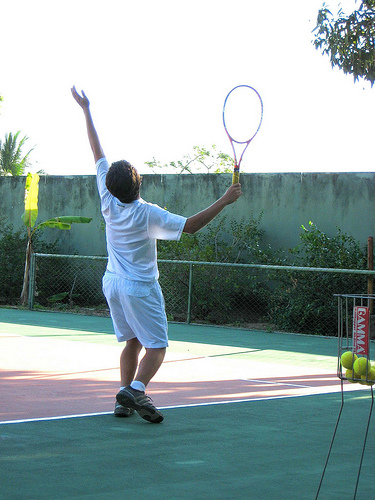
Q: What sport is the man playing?
A: Tennis.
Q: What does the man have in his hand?
A: A tennis racket.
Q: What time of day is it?
A: Daytime.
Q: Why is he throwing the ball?
A: He is serving.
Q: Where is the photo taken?
A: On the tennis court.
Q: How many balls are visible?
A: Four.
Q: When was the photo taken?
A: During the day.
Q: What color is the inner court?
A: Red.